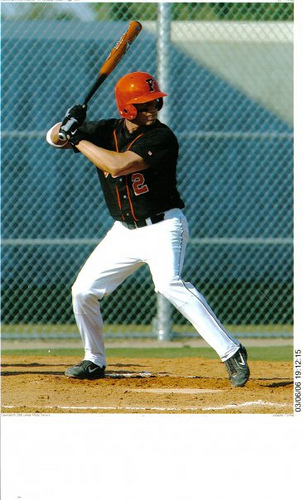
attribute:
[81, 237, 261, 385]
pants — white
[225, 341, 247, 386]
shoe — black, white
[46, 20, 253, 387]
player — of baseball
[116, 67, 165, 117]
helmet — orange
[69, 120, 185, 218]
uniform — baseball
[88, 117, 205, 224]
shirt — black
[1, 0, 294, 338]
fence — silver, chain link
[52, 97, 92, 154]
gloves — black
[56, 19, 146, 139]
bat — brown and black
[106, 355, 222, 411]
dirt — orange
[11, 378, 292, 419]
clay — baseball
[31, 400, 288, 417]
lines — white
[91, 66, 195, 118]
helmet — orange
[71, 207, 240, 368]
pants — white, player's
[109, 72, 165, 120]
helmet — red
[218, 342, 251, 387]
shoe — black, tennis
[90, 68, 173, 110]
helmet — orange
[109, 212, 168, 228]
belt — black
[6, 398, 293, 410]
stripe — white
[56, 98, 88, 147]
gloves — black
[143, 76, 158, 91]
letter — F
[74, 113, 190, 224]
shirt — black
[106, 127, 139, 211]
stripe — orange